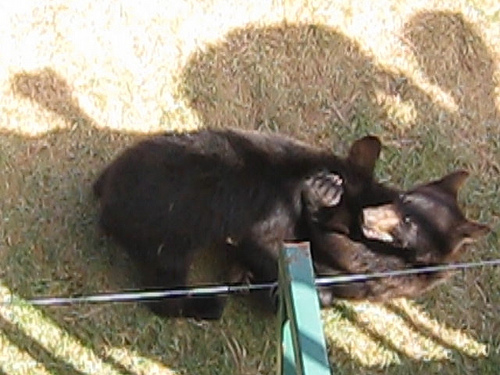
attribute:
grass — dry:
[8, 190, 111, 346]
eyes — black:
[390, 190, 420, 242]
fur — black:
[134, 156, 238, 209]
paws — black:
[300, 144, 350, 222]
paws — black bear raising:
[301, 160, 357, 214]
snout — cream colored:
[358, 199, 398, 245]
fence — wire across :
[8, 221, 483, 371]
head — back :
[352, 148, 475, 312]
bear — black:
[94, 111, 476, 313]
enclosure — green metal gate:
[3, 231, 484, 371]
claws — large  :
[299, 157, 354, 210]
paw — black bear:
[196, 284, 233, 327]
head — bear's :
[376, 157, 480, 293]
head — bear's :
[315, 143, 411, 267]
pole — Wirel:
[278, 242, 330, 364]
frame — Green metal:
[266, 235, 346, 367]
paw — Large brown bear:
[299, 167, 350, 205]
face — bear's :
[361, 189, 470, 256]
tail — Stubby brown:
[81, 165, 128, 213]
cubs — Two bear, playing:
[94, 114, 479, 318]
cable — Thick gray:
[0, 258, 473, 320]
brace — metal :
[267, 241, 326, 372]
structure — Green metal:
[265, 318, 334, 365]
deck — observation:
[10, 264, 250, 310]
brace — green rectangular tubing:
[271, 240, 340, 373]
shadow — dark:
[359, 267, 463, 368]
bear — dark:
[392, 156, 444, 221]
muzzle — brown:
[349, 196, 404, 265]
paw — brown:
[314, 177, 344, 207]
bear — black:
[280, 131, 460, 340]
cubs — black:
[216, 197, 305, 299]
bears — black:
[182, 38, 409, 306]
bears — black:
[249, 60, 400, 290]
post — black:
[309, 253, 338, 305]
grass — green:
[113, 20, 360, 123]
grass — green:
[49, 141, 77, 261]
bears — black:
[107, 82, 349, 264]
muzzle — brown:
[340, 204, 405, 225]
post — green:
[257, 235, 340, 356]